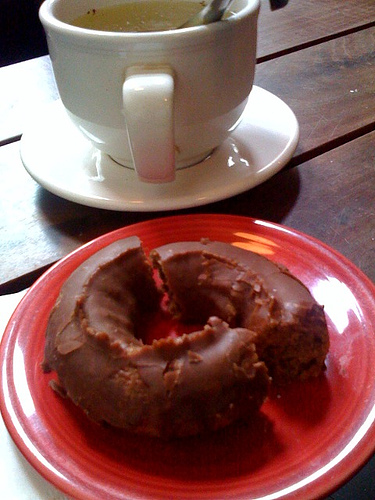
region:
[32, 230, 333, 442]
A donut is in the foreground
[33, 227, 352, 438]
Donut is split in half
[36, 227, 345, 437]
Donut is chocolate covered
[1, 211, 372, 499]
Donut is on a plate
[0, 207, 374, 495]
The plate is red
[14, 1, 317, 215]
A white cup on a plate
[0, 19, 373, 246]
Table is made out of wood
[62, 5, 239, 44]
Liquid is inside the white cup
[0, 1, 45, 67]
The background is black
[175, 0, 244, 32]
Silverware is inside the white cup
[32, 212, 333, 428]
the doughnut is brown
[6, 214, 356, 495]
plate made of porcelain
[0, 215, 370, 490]
the plate is red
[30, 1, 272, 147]
the cup is white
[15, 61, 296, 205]
the plate is white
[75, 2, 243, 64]
yellow liquid in cup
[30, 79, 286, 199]
light reflecting off plate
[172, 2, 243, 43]
utensil in the cup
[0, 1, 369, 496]
table made of wood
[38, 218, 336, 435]
the doughnut is a chocolate doughnut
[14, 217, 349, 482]
a chocolate doughnut on a red plate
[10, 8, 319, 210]
a white cup and saucer with not much beverage in it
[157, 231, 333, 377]
a piece of doughnut that is broken off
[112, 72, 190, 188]
the curved handle of the white cup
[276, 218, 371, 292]
the edge of the red shiny plate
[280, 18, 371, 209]
a dark wooden table with slats in it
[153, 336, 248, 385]
the flaking chocolate frosting on the doughnut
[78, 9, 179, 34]
froth from the beverage that was in the cup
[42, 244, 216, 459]
the larger half of the doughnut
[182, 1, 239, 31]
part of a spoon going into the white cup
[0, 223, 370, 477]
a donut on a red plate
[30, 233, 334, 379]
a chocolate frosted donut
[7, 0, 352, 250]
cup and saucer on the table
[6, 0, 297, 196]
the cup and saucer is white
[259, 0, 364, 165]
the table is brown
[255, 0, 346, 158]
the table is made of wood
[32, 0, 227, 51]
the cup has soup in it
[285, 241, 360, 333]
light reflecting on the plate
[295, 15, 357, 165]
small spaces on the table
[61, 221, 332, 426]
the donut is in 2 pieces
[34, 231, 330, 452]
Broken old fashion chocolate donut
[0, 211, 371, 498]
Shiny red plate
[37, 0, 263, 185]
Dirty white mug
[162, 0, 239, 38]
Silver utensil inside the mug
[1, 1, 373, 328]
Shiny dark wooden table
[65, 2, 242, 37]
Yellowish soup dirties the mug.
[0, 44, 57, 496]
Glare on the table from the window.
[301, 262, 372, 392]
Reflection of the person in the plate.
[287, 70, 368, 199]
Dirt and scratches on the table.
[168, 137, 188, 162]
A dirty smudge on the mug.